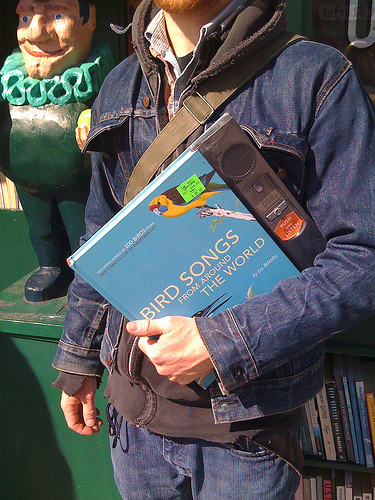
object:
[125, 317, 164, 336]
thumb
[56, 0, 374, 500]
person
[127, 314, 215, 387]
hand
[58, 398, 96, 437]
finger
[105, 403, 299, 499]
jeans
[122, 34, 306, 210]
bag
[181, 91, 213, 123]
buckle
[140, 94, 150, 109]
button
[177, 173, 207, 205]
tag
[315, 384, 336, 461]
book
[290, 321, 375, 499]
shelf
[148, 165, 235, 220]
bird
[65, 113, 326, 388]
book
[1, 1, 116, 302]
statue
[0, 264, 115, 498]
box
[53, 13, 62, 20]
eyes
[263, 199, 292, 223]
button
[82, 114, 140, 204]
pocket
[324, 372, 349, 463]
book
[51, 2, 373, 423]
jacket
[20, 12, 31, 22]
eyes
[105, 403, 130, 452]
string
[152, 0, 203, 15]
beard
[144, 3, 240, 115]
collar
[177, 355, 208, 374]
vein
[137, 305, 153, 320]
letter